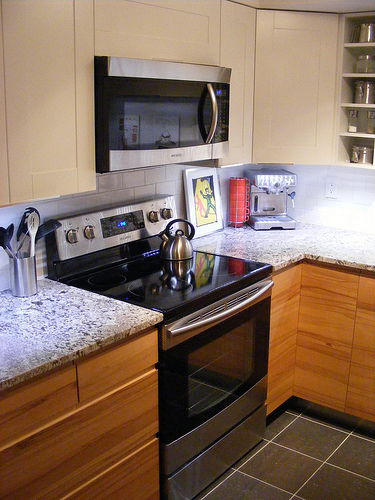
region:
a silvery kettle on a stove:
[154, 219, 214, 260]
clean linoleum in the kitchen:
[279, 428, 370, 494]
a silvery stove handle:
[166, 291, 299, 338]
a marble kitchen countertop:
[2, 303, 161, 367]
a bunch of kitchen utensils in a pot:
[1, 202, 55, 296]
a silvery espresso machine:
[250, 169, 313, 230]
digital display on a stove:
[93, 207, 148, 240]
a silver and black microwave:
[92, 57, 237, 165]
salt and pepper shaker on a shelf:
[346, 107, 374, 136]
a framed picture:
[185, 169, 232, 234]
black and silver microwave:
[96, 57, 232, 170]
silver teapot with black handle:
[157, 218, 196, 260]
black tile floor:
[180, 398, 373, 498]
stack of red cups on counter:
[227, 176, 248, 227]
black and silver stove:
[44, 192, 271, 497]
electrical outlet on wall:
[324, 174, 337, 198]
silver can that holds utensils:
[9, 250, 37, 296]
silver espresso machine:
[248, 167, 299, 229]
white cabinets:
[0, 0, 372, 204]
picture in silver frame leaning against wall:
[184, 166, 224, 237]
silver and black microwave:
[94, 55, 232, 162]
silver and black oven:
[50, 192, 268, 495]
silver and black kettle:
[158, 216, 197, 259]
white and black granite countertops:
[2, 219, 373, 386]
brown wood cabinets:
[266, 260, 373, 413]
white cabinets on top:
[0, 0, 373, 169]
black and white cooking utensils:
[1, 204, 57, 295]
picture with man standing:
[183, 167, 221, 232]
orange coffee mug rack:
[230, 175, 251, 228]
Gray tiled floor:
[271, 429, 368, 499]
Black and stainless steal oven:
[154, 298, 287, 480]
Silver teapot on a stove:
[152, 213, 205, 263]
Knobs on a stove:
[60, 216, 113, 248]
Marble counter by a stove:
[7, 297, 123, 346]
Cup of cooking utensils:
[0, 203, 54, 291]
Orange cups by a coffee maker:
[227, 173, 252, 233]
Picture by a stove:
[183, 165, 235, 244]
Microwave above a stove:
[99, 49, 243, 163]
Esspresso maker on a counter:
[242, 168, 297, 233]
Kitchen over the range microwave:
[100, 52, 232, 170]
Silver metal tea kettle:
[158, 216, 197, 263]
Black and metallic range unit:
[47, 192, 274, 498]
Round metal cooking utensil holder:
[0, 206, 60, 297]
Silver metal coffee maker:
[244, 167, 300, 231]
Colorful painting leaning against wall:
[180, 164, 229, 241]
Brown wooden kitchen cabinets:
[268, 249, 374, 424]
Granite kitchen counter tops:
[193, 210, 374, 272]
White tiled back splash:
[94, 161, 188, 197]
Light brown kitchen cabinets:
[246, 5, 372, 167]